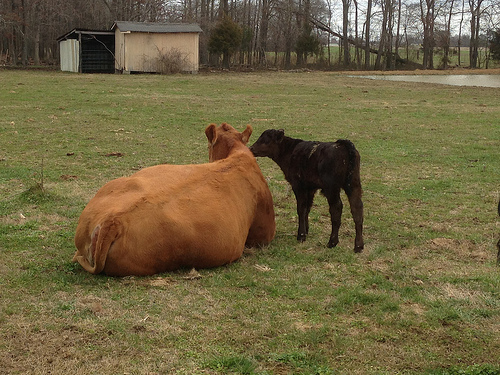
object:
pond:
[361, 72, 499, 93]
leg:
[322, 185, 343, 248]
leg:
[342, 179, 364, 254]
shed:
[56, 27, 118, 72]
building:
[110, 21, 202, 74]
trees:
[373, 0, 391, 71]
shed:
[110, 20, 206, 76]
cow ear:
[241, 124, 253, 146]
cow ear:
[204, 123, 218, 148]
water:
[354, 73, 500, 90]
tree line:
[214, 56, 497, 73]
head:
[248, 127, 287, 158]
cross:
[67, 122, 365, 279]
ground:
[0, 69, 500, 375]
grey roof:
[114, 19, 202, 34]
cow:
[69, 124, 276, 278]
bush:
[144, 43, 193, 75]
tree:
[206, 13, 243, 69]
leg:
[293, 186, 309, 241]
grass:
[2, 67, 499, 375]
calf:
[249, 128, 363, 252]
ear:
[276, 131, 285, 140]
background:
[0, 0, 498, 78]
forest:
[0, 0, 494, 71]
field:
[0, 66, 500, 375]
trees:
[468, 0, 478, 67]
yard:
[0, 70, 500, 375]